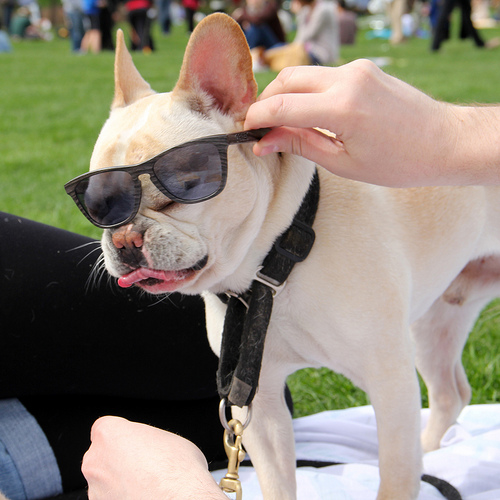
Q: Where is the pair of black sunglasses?
A: On the dog.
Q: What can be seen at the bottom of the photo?
A: A person's hand.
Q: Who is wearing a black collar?
A: The dog.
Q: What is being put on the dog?
A: Sunglasses.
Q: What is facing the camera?
A: The white dog.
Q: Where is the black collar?
A: On the dog.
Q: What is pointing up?
A: The ear of the white dog.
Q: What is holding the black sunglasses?
A: A hand.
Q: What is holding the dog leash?
A: A hand.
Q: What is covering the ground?
A: Green grass.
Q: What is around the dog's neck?
A: A collar.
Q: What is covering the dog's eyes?
A: Sunglasses.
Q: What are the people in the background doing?
A: Having a picnic.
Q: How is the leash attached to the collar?
A: With a clip.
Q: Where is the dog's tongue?
A: Hanging out of its mouth.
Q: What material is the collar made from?
A: Nylon webbing.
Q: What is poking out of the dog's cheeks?
A: Whiskers.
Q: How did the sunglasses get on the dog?
A: A person just put them on.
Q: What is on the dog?
A: Sunglasses.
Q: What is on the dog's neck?
A: Collar.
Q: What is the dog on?
A: Blanket.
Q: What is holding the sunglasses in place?
A: A hand.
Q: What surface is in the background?
A: Grass.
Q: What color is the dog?
A: White.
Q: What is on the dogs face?
A: Glasses.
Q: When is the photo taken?
A: Day time.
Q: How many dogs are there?
A: One.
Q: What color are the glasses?
A: Black.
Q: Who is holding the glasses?
A: The man.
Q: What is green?
A: The grass.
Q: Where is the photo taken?
A: At a park.